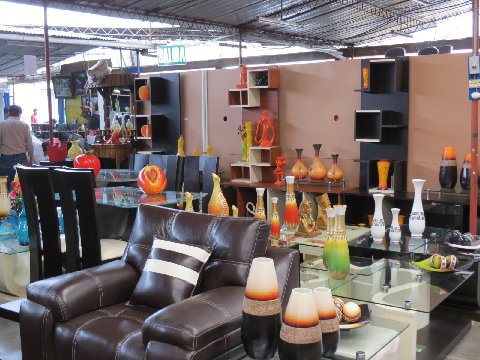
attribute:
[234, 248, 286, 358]
candle holder — white, orange, black, brown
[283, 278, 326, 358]
candle holder — white, orange, black, brown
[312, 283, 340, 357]
candle holder — white, orange, black, brown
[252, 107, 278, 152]
orange object — weird shape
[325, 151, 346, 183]
vase — orange, brown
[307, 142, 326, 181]
vase — orange, brown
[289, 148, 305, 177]
vase — orange, brown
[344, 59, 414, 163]
shelves — brown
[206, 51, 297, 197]
shelf — white, pink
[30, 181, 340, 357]
chair — brown, leather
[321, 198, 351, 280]
vase — green, yellow, tan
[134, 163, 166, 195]
sculpture — orange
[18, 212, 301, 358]
chair — brown, leather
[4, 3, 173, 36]
light — falling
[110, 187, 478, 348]
table — glass, rectangular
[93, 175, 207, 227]
table — glass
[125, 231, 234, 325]
pillow — brown, white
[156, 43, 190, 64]
sign — white, green, hanging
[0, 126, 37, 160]
shirt — white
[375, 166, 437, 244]
vases — white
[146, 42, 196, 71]
sign — green, white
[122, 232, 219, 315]
pillow — brown, white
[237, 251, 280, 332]
light — small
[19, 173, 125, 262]
chair — wooden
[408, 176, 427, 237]
vase — white, gray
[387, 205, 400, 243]
vase — white, gray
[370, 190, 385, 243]
vase — white, gray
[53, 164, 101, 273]
chair — black, white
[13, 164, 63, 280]
chair — black, white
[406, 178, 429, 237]
vase — white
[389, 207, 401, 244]
vase — white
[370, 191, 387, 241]
vase — white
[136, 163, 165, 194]
vase — orange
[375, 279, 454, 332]
base — white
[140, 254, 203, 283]
line — white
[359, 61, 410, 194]
door — long